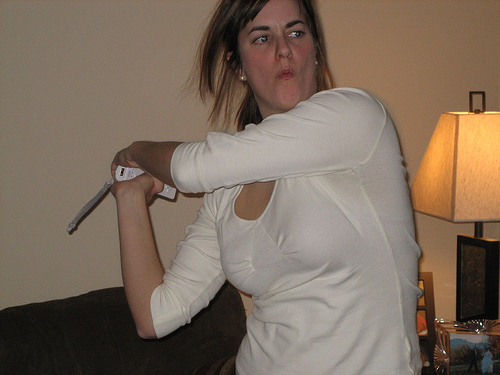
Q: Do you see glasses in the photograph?
A: No, there are no glasses.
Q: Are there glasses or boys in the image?
A: No, there are no glasses or boys.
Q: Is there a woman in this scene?
A: Yes, there is a woman.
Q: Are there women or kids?
A: Yes, there is a woman.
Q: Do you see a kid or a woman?
A: Yes, there is a woman.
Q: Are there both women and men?
A: No, there is a woman but no men.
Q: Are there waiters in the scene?
A: No, there are no waiters.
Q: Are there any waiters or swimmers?
A: No, there are no waiters or swimmers.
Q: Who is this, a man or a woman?
A: This is a woman.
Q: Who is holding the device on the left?
A: The woman is holding the controller.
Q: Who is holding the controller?
A: The woman is holding the controller.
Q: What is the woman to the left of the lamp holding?
A: The woman is holding the controller.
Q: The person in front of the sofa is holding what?
A: The woman is holding the controller.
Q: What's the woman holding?
A: The woman is holding the controller.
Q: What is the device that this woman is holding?
A: The device is a controller.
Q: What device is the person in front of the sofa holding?
A: The woman is holding the controller.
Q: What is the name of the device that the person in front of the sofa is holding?
A: The device is a controller.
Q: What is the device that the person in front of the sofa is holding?
A: The device is a controller.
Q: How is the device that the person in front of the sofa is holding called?
A: The device is a controller.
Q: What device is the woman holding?
A: The woman is holding the controller.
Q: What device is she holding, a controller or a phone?
A: The woman is holding a controller.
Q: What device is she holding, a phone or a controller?
A: The woman is holding a controller.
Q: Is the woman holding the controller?
A: Yes, the woman is holding the controller.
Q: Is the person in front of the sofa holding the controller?
A: Yes, the woman is holding the controller.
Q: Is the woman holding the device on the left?
A: Yes, the woman is holding the controller.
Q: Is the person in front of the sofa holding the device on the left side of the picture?
A: Yes, the woman is holding the controller.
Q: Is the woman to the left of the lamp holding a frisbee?
A: No, the woman is holding the controller.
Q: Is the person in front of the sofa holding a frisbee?
A: No, the woman is holding the controller.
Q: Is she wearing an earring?
A: Yes, the woman is wearing an earring.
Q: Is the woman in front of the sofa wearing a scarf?
A: No, the woman is wearing an earring.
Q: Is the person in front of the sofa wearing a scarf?
A: No, the woman is wearing an earring.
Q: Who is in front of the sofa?
A: The woman is in front of the sofa.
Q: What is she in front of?
A: The woman is in front of the sofa.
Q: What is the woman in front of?
A: The woman is in front of the sofa.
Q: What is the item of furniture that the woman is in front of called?
A: The piece of furniture is a sofa.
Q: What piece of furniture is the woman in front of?
A: The woman is in front of the sofa.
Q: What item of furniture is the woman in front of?
A: The woman is in front of the sofa.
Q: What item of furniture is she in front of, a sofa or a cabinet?
A: The woman is in front of a sofa.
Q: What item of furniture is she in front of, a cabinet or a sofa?
A: The woman is in front of a sofa.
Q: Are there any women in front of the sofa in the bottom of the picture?
A: Yes, there is a woman in front of the sofa.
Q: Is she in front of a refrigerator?
A: No, the woman is in front of the sofa.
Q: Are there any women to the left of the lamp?
A: Yes, there is a woman to the left of the lamp.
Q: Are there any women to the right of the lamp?
A: No, the woman is to the left of the lamp.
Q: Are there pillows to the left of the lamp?
A: No, there is a woman to the left of the lamp.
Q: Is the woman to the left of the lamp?
A: Yes, the woman is to the left of the lamp.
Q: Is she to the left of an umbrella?
A: No, the woman is to the left of the lamp.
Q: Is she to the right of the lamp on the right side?
A: No, the woman is to the left of the lamp.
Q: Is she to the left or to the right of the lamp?
A: The woman is to the left of the lamp.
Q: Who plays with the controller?
A: The woman plays with the controller.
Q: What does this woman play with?
A: The woman plays with a controller.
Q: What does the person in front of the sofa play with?
A: The woman plays with a controller.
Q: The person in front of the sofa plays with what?
A: The woman plays with a controller.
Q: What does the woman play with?
A: The woman plays with a controller.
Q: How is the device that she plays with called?
A: The device is a controller.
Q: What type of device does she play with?
A: The woman plays with a controller.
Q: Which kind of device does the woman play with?
A: The woman plays with a controller.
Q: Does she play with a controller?
A: Yes, the woman plays with a controller.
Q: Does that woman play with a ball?
A: No, the woman plays with a controller.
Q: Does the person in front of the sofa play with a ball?
A: No, the woman plays with a controller.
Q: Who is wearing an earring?
A: The woman is wearing an earring.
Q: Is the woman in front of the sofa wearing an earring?
A: Yes, the woman is wearing an earring.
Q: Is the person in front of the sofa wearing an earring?
A: Yes, the woman is wearing an earring.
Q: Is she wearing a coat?
A: No, the woman is wearing an earring.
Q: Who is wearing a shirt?
A: The woman is wearing a shirt.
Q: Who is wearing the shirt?
A: The woman is wearing a shirt.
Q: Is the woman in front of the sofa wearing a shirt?
A: Yes, the woman is wearing a shirt.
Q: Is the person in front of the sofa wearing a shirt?
A: Yes, the woman is wearing a shirt.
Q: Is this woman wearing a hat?
A: No, the woman is wearing a shirt.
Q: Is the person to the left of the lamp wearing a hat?
A: No, the woman is wearing a shirt.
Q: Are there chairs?
A: Yes, there is a chair.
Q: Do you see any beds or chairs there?
A: Yes, there is a chair.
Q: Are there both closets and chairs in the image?
A: No, there is a chair but no closets.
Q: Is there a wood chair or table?
A: Yes, there is a wood chair.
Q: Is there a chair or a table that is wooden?
A: Yes, the chair is wooden.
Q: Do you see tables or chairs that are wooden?
A: Yes, the chair is wooden.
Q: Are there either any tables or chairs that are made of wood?
A: Yes, the chair is made of wood.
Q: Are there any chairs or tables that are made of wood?
A: Yes, the chair is made of wood.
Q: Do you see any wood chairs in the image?
A: Yes, there is a wood chair.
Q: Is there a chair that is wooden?
A: Yes, there is a chair that is wooden.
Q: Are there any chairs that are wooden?
A: Yes, there is a chair that is wooden.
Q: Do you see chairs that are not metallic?
A: Yes, there is a wooden chair.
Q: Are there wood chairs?
A: Yes, there is a chair that is made of wood.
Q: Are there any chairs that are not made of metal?
A: Yes, there is a chair that is made of wood.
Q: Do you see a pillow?
A: No, there are no pillows.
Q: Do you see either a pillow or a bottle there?
A: No, there are no pillows or bottles.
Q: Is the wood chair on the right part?
A: Yes, the chair is on the right of the image.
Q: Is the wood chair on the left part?
A: No, the chair is on the right of the image.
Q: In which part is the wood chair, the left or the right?
A: The chair is on the right of the image.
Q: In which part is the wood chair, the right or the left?
A: The chair is on the right of the image.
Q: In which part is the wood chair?
A: The chair is on the right of the image.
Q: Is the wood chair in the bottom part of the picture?
A: Yes, the chair is in the bottom of the image.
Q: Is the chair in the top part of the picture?
A: No, the chair is in the bottom of the image.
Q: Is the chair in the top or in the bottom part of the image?
A: The chair is in the bottom of the image.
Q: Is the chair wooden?
A: Yes, the chair is wooden.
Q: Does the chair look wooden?
A: Yes, the chair is wooden.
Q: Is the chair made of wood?
A: Yes, the chair is made of wood.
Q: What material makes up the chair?
A: The chair is made of wood.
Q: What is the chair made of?
A: The chair is made of wood.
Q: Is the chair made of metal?
A: No, the chair is made of wood.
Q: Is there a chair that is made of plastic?
A: No, there is a chair but it is made of wood.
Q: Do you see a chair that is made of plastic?
A: No, there is a chair but it is made of wood.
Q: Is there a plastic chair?
A: No, there is a chair but it is made of wood.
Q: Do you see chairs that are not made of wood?
A: No, there is a chair but it is made of wood.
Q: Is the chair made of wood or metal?
A: The chair is made of wood.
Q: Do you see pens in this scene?
A: No, there are no pens.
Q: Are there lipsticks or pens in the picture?
A: No, there are no pens or lipsticks.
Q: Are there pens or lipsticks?
A: No, there are no pens or lipsticks.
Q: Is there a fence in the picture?
A: No, there are no fences.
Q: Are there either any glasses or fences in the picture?
A: No, there are no fences or glasses.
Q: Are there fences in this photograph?
A: No, there are no fences.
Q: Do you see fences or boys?
A: No, there are no fences or boys.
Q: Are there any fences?
A: No, there are no fences.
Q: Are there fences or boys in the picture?
A: No, there are no fences or boys.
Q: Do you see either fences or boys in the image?
A: No, there are no fences or boys.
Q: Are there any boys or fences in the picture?
A: No, there are no fences or boys.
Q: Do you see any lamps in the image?
A: Yes, there is a lamp.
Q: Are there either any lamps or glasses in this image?
A: Yes, there is a lamp.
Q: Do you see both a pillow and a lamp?
A: No, there is a lamp but no pillows.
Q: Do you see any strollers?
A: No, there are no strollers.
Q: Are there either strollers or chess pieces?
A: No, there are no strollers or chess pieces.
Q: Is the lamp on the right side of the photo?
A: Yes, the lamp is on the right of the image.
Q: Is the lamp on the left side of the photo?
A: No, the lamp is on the right of the image.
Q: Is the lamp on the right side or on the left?
A: The lamp is on the right of the image.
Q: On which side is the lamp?
A: The lamp is on the right of the image.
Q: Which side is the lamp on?
A: The lamp is on the right of the image.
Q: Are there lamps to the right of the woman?
A: Yes, there is a lamp to the right of the woman.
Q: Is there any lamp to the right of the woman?
A: Yes, there is a lamp to the right of the woman.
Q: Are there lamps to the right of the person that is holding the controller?
A: Yes, there is a lamp to the right of the woman.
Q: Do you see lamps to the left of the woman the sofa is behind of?
A: No, the lamp is to the right of the woman.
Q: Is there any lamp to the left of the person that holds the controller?
A: No, the lamp is to the right of the woman.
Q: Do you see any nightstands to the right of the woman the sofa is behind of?
A: No, there is a lamp to the right of the woman.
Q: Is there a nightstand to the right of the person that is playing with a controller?
A: No, there is a lamp to the right of the woman.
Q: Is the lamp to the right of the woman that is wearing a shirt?
A: Yes, the lamp is to the right of the woman.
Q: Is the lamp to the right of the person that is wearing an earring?
A: Yes, the lamp is to the right of the woman.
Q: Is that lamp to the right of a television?
A: No, the lamp is to the right of the woman.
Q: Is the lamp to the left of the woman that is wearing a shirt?
A: No, the lamp is to the right of the woman.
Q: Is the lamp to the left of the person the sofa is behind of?
A: No, the lamp is to the right of the woman.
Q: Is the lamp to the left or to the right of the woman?
A: The lamp is to the right of the woman.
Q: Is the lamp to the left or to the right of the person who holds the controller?
A: The lamp is to the right of the woman.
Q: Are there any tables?
A: Yes, there is a table.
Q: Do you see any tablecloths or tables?
A: Yes, there is a table.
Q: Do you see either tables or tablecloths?
A: Yes, there is a table.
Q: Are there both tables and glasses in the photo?
A: No, there is a table but no glasses.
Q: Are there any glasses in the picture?
A: No, there are no glasses.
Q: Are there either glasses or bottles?
A: No, there are no glasses or bottles.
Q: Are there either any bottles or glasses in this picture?
A: No, there are no glasses or bottles.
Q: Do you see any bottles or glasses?
A: No, there are no glasses or bottles.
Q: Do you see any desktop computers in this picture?
A: No, there are no desktop computers.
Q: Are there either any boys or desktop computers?
A: No, there are no desktop computers or boys.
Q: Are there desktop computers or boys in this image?
A: No, there are no desktop computers or boys.